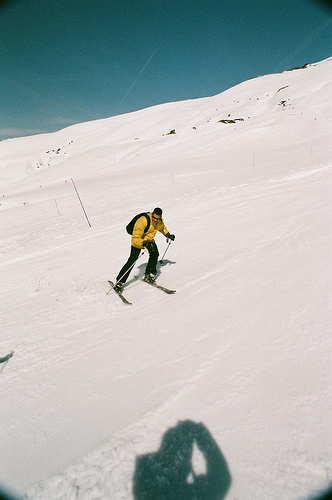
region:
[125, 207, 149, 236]
Black back pack on the skier's back.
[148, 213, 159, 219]
The sunglasses the skier is wearing.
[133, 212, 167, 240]
The yellow coat the skier is wearing.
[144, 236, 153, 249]
The left glove the skier is wearing.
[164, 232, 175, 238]
The right glove the skier is wearing.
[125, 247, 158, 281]
The black pants the skier is wearing.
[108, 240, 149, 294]
Left ski pole.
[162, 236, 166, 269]
The right ski pole.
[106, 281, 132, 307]
The left ski the skier is standing on.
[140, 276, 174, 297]
The right ski the skier is standing on.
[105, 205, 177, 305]
a man on skis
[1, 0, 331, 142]
a cloudless blue sky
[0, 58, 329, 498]
snow covered slope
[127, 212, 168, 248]
a yellow ski jacket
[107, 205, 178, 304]
skier is looking down the slope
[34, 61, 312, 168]
snow covered rocks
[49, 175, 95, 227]
poles marking the course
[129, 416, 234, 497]
shadow of a person on the snow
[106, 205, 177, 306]
skier wearing black pants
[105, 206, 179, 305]
skier with a black backpack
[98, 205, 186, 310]
Male skier wearing a yellow jacket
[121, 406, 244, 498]
Shadow of a person taking a picture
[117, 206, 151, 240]
Black backpack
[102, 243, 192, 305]
Set of skies and poles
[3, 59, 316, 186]
Mountain covered in snow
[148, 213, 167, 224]
Snow goggles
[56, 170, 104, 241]
Skiing pole in the snow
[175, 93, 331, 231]
White snow covering the mountain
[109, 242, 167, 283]
Black ski pants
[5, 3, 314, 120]
Dark blue sky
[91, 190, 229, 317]
the man is skiing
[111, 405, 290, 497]
shadow of person with camera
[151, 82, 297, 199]
a lot of snow on hill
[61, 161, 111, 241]
pole in the snow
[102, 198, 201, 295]
man is wearing yellow jacket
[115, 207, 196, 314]
man has black backpack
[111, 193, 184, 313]
man is wearing sunglasses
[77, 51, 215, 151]
the sky is blue against snow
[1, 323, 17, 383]
arm of skier with pole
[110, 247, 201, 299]
shadow of skier in snow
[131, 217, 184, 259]
Person is wearing yellow jacket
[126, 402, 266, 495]
A person's shadow in the snow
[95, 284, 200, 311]
Two skis on person's feet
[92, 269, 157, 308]
Person holding ski poles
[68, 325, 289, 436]
Ground is covered in white snow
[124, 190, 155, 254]
Person is wearing black back pack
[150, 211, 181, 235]
Sunglasses on man's face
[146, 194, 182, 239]
Person has dark hair on head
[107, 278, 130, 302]
Person is wearing dark boots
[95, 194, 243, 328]
Man is skiing down a mountain